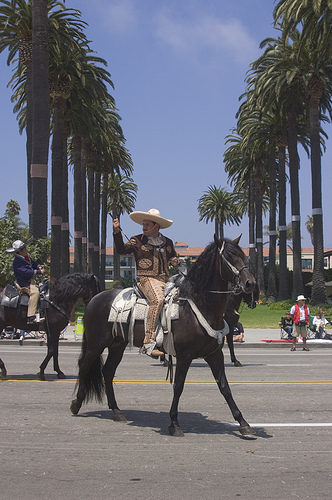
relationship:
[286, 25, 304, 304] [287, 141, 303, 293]
tree has trunk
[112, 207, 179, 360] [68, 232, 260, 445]
man on horse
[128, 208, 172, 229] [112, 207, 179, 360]
hat on man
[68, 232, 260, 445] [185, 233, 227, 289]
horse has mane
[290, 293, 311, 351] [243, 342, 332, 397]
man on road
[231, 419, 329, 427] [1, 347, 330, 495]
line on road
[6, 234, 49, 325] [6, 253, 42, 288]
man wears jacket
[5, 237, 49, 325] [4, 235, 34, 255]
man wearing hat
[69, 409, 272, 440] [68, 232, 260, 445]
shadow of horse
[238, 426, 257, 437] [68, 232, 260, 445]
hoof of horse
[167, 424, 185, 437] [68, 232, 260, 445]
hoof of horse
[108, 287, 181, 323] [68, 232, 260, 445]
saddle on horse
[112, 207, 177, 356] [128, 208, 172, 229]
man wearing hat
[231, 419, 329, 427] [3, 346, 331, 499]
line on street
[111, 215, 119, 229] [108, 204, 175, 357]
hand of man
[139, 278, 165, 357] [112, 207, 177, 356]
leg of man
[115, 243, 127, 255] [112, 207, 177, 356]
elbow of man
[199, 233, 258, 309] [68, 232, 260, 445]
head of horse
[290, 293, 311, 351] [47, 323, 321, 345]
man on sidewalk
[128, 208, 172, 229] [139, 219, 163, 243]
hat on head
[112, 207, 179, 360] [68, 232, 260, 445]
man riding a horse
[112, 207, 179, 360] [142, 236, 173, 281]
man wearing brown top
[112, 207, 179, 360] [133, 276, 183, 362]
man wearing pants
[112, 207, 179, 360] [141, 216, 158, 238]
man has head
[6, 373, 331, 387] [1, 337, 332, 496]
line on road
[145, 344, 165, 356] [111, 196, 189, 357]
foot of man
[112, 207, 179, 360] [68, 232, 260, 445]
man riding horse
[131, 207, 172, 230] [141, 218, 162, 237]
hat on head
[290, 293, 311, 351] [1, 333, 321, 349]
man in front of curb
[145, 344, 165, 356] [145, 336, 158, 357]
foot in stirrup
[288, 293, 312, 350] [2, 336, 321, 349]
man by curb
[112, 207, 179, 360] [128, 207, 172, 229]
man wearing sombero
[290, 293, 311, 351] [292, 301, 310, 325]
man wearing vest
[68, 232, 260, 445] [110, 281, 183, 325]
horse has blanket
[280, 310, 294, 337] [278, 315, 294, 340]
boy in chair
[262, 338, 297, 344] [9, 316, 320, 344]
towel on sidewalk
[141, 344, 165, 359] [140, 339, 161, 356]
foot in stirrup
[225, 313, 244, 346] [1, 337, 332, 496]
person on road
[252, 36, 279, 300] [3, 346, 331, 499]
tree near street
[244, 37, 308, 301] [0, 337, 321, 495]
tree near street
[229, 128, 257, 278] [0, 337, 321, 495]
tree near street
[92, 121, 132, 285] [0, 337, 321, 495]
tree near street